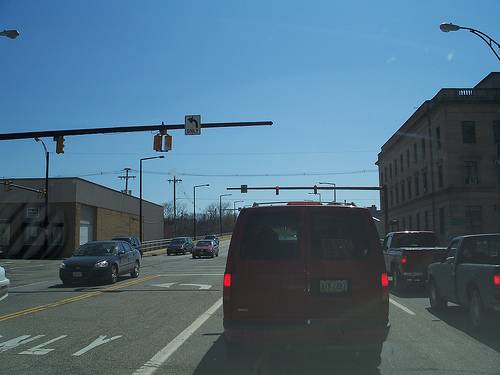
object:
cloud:
[0, 11, 499, 177]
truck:
[383, 230, 459, 290]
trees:
[160, 197, 235, 235]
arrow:
[151, 281, 212, 289]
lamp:
[139, 155, 167, 243]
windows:
[403, 150, 446, 185]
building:
[375, 70, 500, 246]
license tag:
[319, 279, 348, 293]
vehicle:
[222, 204, 389, 354]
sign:
[185, 115, 201, 135]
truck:
[424, 232, 500, 331]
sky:
[0, 0, 499, 216]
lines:
[1, 270, 238, 372]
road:
[2, 239, 497, 374]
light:
[224, 273, 231, 286]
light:
[381, 273, 387, 285]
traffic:
[0, 199, 499, 373]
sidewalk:
[135, 247, 167, 256]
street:
[0, 237, 499, 374]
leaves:
[208, 197, 233, 223]